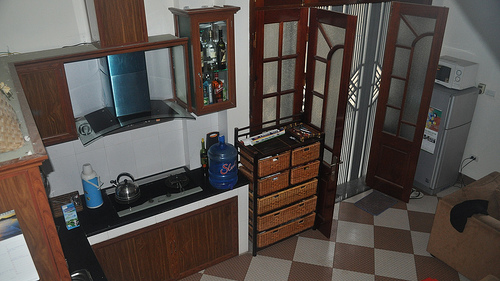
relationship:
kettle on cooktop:
[108, 172, 140, 202] [103, 163, 202, 216]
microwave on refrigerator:
[437, 51, 477, 93] [416, 79, 482, 201]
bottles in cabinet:
[201, 36, 227, 104] [165, 2, 242, 111]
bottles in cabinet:
[202, 132, 239, 185] [165, 2, 242, 111]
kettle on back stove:
[108, 172, 140, 202] [79, 164, 218, 241]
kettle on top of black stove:
[108, 172, 140, 202] [89, 157, 201, 213]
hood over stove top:
[74, 51, 194, 146] [96, 164, 203, 214]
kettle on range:
[106, 170, 148, 202] [103, 160, 200, 221]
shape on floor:
[300, 211, 341, 245] [189, 192, 436, 277]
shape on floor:
[203, 250, 254, 277] [122, 177, 498, 279]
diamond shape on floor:
[372, 224, 414, 254] [177, 181, 473, 279]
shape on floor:
[421, 254, 462, 279] [164, 175, 470, 278]